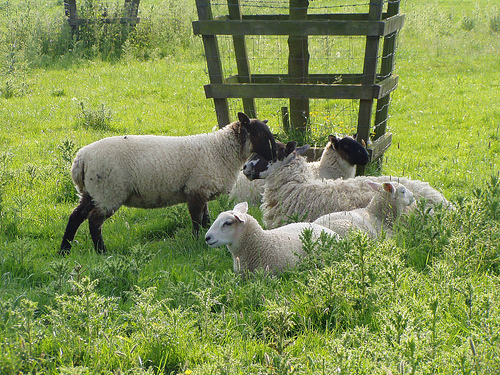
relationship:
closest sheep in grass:
[204, 201, 341, 278] [10, 215, 496, 370]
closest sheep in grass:
[204, 201, 341, 278] [0, 0, 497, 374]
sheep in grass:
[60, 111, 279, 256] [122, 191, 493, 337]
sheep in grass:
[60, 111, 279, 256] [2, 60, 493, 374]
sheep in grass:
[60, 111, 279, 256] [38, 220, 244, 316]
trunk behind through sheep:
[283, 4, 313, 134] [70, 115, 437, 277]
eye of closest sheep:
[221, 217, 234, 227] [201, 200, 341, 277]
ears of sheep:
[364, 175, 396, 195] [314, 178, 417, 238]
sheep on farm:
[60, 111, 279, 256] [1, 0, 498, 373]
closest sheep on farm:
[204, 201, 341, 278] [1, 0, 498, 373]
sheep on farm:
[242, 140, 458, 230] [1, 0, 498, 373]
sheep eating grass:
[60, 111, 279, 256] [326, 269, 408, 334]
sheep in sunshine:
[241, 141, 457, 230] [2, 0, 484, 372]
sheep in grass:
[60, 111, 279, 256] [0, 0, 499, 375]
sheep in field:
[241, 141, 457, 230] [0, 6, 497, 373]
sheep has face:
[60, 111, 279, 256] [239, 111, 278, 156]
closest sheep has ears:
[204, 201, 341, 278] [231, 198, 251, 226]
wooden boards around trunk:
[184, 26, 463, 148] [287, 7, 313, 146]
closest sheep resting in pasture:
[204, 201, 341, 278] [1, 270, 498, 373]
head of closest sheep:
[203, 210, 249, 247] [204, 201, 341, 278]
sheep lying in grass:
[60, 111, 279, 256] [282, 257, 432, 352]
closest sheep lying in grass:
[204, 201, 341, 278] [334, 276, 434, 359]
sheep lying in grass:
[311, 175, 416, 246] [334, 276, 434, 359]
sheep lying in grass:
[307, 124, 372, 180] [334, 276, 434, 359]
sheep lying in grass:
[60, 111, 279, 256] [334, 276, 434, 359]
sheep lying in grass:
[241, 141, 457, 230] [334, 276, 434, 359]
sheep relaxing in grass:
[60, 111, 279, 256] [181, 254, 499, 364]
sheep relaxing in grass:
[242, 140, 458, 230] [181, 254, 499, 364]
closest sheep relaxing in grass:
[204, 201, 341, 278] [181, 254, 499, 364]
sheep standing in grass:
[60, 111, 279, 256] [93, 262, 450, 361]